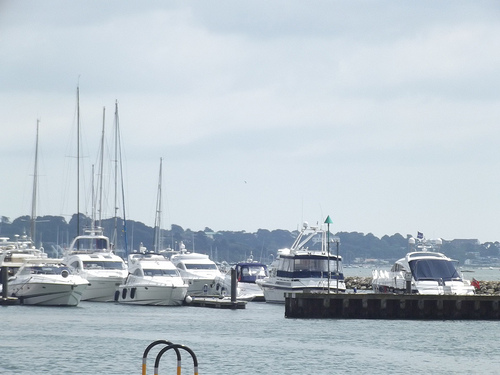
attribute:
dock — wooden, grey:
[191, 287, 265, 308]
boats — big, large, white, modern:
[14, 230, 471, 310]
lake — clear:
[6, 302, 497, 373]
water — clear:
[7, 304, 499, 368]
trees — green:
[1, 213, 499, 261]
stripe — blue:
[21, 291, 87, 300]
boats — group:
[30, 231, 246, 311]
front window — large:
[404, 257, 457, 280]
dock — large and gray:
[281, 289, 498, 321]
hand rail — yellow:
[136, 334, 201, 372]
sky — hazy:
[119, 81, 388, 265]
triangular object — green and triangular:
[322, 215, 332, 227]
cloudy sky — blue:
[0, 0, 499, 247]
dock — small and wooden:
[180, 226, 307, 299]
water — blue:
[102, 314, 316, 357]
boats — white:
[7, 215, 227, 310]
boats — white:
[2, 53, 246, 345]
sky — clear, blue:
[1, 0, 490, 235]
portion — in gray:
[151, 347, 194, 375]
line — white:
[35, 327, 482, 368]